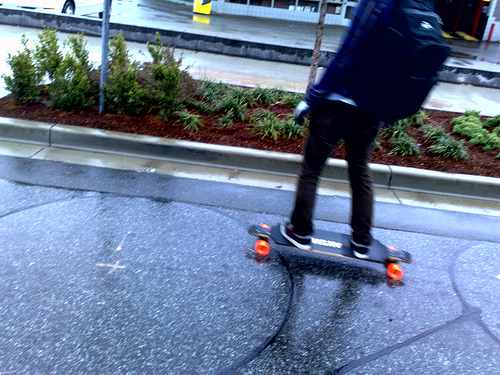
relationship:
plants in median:
[4, 28, 287, 142] [0, 18, 499, 198]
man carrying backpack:
[279, 0, 455, 261] [351, 0, 453, 129]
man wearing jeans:
[279, 0, 455, 261] [293, 97, 381, 247]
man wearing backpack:
[279, 0, 455, 261] [298, 3, 454, 130]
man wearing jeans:
[279, 0, 455, 261] [293, 97, 384, 259]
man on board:
[279, 0, 455, 261] [248, 223, 413, 283]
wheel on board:
[386, 262, 405, 280] [248, 222, 412, 264]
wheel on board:
[254, 238, 269, 255] [248, 222, 412, 264]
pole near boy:
[94, 2, 115, 114] [278, 0, 455, 258]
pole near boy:
[304, 0, 331, 87] [278, 0, 455, 258]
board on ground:
[248, 223, 413, 283] [0, 137, 499, 372]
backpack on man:
[356, 2, 445, 115] [279, 0, 395, 256]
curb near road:
[1, 115, 498, 200] [1, 137, 498, 374]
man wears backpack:
[279, 0, 455, 261] [356, 2, 453, 125]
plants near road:
[4, 28, 287, 142] [21, 137, 498, 359]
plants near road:
[380, 107, 482, 148] [21, 137, 498, 359]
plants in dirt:
[4, 28, 287, 142] [42, 102, 164, 134]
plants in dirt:
[4, 28, 287, 142] [200, 117, 481, 161]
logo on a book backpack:
[412, 15, 432, 32] [356, 2, 453, 125]